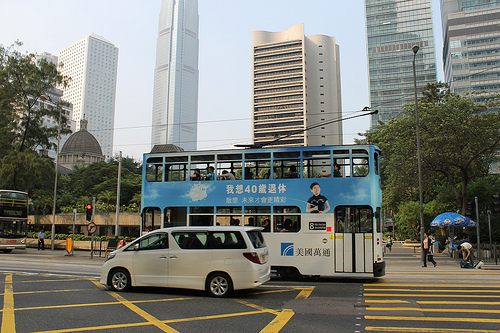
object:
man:
[37, 230, 44, 250]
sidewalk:
[11, 228, 110, 257]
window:
[246, 230, 267, 248]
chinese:
[296, 247, 304, 256]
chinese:
[305, 248, 313, 257]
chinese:
[313, 248, 322, 257]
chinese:
[322, 248, 331, 257]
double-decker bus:
[140, 144, 386, 281]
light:
[86, 203, 93, 222]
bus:
[140, 144, 386, 278]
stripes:
[0, 270, 316, 333]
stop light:
[85, 203, 92, 221]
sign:
[87, 222, 97, 234]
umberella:
[429, 211, 477, 229]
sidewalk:
[384, 238, 500, 270]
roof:
[58, 116, 105, 154]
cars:
[100, 226, 270, 296]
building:
[6, 52, 76, 164]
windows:
[428, 29, 433, 36]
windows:
[424, 48, 429, 53]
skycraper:
[149, 0, 199, 159]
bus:
[0, 189, 31, 249]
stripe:
[362, 282, 499, 287]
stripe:
[363, 292, 499, 297]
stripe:
[364, 306, 499, 313]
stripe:
[364, 314, 500, 323]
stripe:
[363, 325, 500, 333]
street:
[1, 270, 498, 333]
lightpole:
[412, 44, 426, 267]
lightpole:
[50, 104, 62, 252]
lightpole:
[264, 108, 378, 146]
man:
[306, 182, 331, 214]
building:
[57, 113, 107, 173]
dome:
[57, 113, 104, 155]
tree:
[352, 80, 500, 241]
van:
[99, 225, 272, 297]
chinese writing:
[226, 184, 287, 204]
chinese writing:
[295, 247, 330, 256]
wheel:
[206, 273, 234, 298]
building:
[251, 23, 344, 177]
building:
[150, 0, 199, 177]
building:
[56, 32, 119, 163]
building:
[363, 0, 439, 132]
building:
[439, 0, 499, 176]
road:
[0, 261, 499, 333]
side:
[139, 142, 382, 277]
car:
[100, 225, 272, 296]